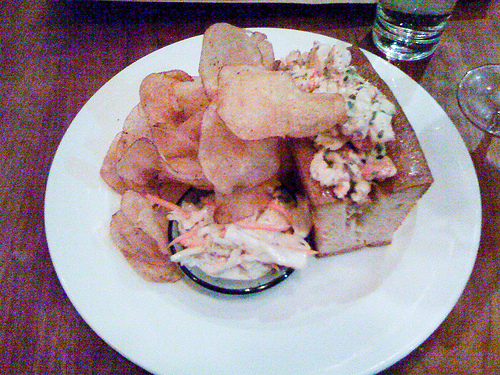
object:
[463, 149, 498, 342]
shadow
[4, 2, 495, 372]
table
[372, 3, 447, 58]
water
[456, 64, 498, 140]
bottom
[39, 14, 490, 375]
plate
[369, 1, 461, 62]
cup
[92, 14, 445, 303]
food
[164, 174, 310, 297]
dish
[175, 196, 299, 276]
coleslaw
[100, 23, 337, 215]
chips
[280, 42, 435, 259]
bun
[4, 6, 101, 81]
brown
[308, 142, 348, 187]
shrimp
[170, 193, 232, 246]
carrot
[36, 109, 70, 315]
edge